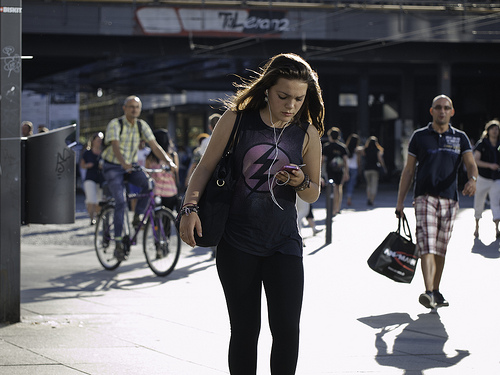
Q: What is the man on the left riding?
A: A bicycle.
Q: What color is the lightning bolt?
A: Black.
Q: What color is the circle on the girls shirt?
A: Pink.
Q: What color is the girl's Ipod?
A: Pink.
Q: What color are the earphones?
A: White.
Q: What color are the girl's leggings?
A: Black.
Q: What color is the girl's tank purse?
A: Black.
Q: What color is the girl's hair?
A: Brown.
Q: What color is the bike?
A: Purple.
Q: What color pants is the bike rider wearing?
A: Blue.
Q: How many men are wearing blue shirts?
A: One.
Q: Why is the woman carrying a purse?
A: Protection.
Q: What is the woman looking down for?
A: Phone.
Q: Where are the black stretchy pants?
A: On the girl.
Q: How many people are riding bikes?
A: One.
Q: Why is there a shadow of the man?
A: Sunny.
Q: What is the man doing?
A: Walking.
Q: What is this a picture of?
A: Lady walking.